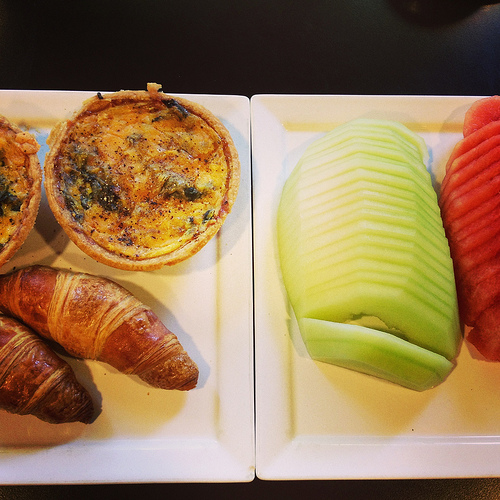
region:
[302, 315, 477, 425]
slices of fruit on plate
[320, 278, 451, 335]
slices of fruit on plate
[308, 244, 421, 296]
slices of fruit on plate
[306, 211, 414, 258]
slices of fruit on plate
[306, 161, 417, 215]
slices of fruit on plate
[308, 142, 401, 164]
slices of fruit on plate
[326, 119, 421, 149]
slices of fruit on plate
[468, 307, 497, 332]
slices of fruit on plate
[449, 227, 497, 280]
slices of fruit on plate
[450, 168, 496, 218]
slices of fruit on plate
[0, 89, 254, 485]
a white square plate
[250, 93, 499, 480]
a white square plate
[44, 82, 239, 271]
a small quiche on the plate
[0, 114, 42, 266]
a small quiche on the plate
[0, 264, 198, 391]
a croissant on the plate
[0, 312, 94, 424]
a croissant on the plate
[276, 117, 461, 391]
a slided honeydew melon on a plate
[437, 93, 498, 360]
a slided watermelon on a plate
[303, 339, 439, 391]
a slice of honeydew melon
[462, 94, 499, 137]
a slice of watermelon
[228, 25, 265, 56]
this is a table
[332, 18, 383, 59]
the table is black in color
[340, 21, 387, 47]
the table is clean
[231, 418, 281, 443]
this is a tray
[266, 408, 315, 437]
the tray is white in color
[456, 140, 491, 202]
these are the tomatoes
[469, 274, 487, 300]
the tomato is red in color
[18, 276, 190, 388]
this is some bread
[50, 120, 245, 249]
this is a pie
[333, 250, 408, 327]
this is some food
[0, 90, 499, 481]
Various types of breakfast foods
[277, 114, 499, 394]
Fruit is sliced thinly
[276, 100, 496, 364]
Fruit is red and green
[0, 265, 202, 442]
Two croissants are on plate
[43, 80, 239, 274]
A small quiche is on the plate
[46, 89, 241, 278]
The quiche is round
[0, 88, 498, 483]
There are a total of two plates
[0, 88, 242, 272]
Two quiches will be eaten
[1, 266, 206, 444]
Two croissants will be eaten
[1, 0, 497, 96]
The table is black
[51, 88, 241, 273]
Round yellow quiche on white plate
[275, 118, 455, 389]
Sliced green melon on white plate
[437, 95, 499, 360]
Sliced red watermelon on white plate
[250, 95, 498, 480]
Sliced fruit on square white plate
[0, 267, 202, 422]
Brown croissant rolls on white plate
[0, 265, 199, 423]
Two croissant rolls on white plate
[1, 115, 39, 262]
Piece of round quiche at edge of plate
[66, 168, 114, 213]
Black burnt spot on quiche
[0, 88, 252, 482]
Quiche and croissants on square white plate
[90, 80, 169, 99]
Flaky crust on edge of quiche